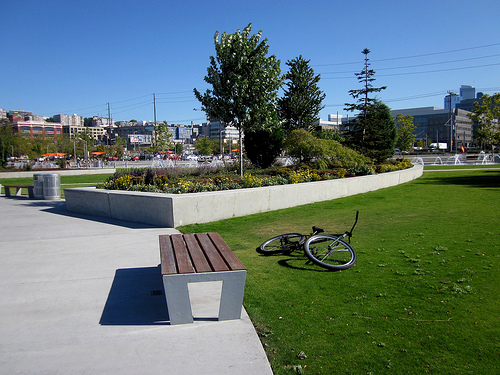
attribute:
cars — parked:
[101, 129, 227, 186]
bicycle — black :
[248, 207, 362, 282]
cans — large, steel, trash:
[31, 166, 66, 201]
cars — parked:
[113, 147, 198, 164]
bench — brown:
[140, 203, 283, 308]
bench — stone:
[156, 232, 248, 327]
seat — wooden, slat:
[155, 230, 246, 277]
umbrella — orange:
[40, 149, 65, 159]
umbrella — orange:
[87, 149, 104, 154]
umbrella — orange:
[155, 147, 170, 154]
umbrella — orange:
[230, 146, 247, 152]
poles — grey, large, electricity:
[105, 75, 271, 167]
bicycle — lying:
[255, 213, 380, 286]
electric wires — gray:
[108, 37, 498, 115]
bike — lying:
[257, 208, 367, 271]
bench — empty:
[150, 223, 259, 342]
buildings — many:
[2, 105, 240, 160]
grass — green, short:
[260, 189, 497, 366]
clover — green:
[396, 246, 405, 253]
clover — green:
[376, 291, 388, 298]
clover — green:
[456, 275, 466, 282]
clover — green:
[433, 242, 448, 252]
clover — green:
[375, 260, 390, 265]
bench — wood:
[155, 227, 255, 331]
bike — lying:
[244, 204, 358, 272]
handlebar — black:
[346, 217, 374, 242]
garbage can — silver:
[40, 172, 62, 203]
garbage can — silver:
[31, 174, 43, 201]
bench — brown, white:
[144, 230, 254, 323]